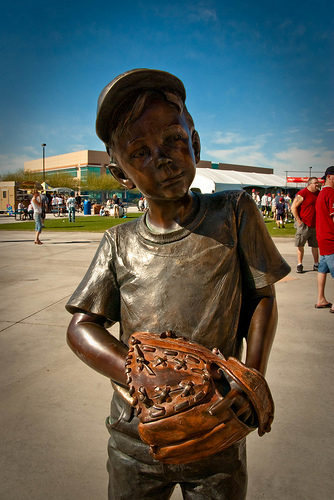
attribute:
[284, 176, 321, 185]
sign — red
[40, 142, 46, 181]
light post — in distance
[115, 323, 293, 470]
glove — detailed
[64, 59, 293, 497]
statue — copper, bronze, shining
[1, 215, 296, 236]
field — large, green, grassy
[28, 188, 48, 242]
woman — in background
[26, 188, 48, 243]
woman — standing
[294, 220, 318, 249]
shorts — grey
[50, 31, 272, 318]
boy statue — looking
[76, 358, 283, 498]
jeans — blue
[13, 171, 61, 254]
woman — standing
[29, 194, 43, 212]
shirt — white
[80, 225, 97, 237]
grass — green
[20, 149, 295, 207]
building — background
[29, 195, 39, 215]
tanktop — white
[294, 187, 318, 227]
shirt — red